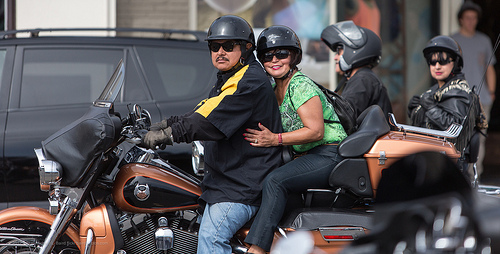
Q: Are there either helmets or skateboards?
A: Yes, there is a helmet.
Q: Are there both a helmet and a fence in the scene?
A: No, there is a helmet but no fences.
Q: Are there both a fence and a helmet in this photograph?
A: No, there is a helmet but no fences.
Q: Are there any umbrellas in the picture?
A: No, there are no umbrellas.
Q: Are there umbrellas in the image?
A: No, there are no umbrellas.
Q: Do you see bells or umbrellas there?
A: No, there are no umbrellas or bells.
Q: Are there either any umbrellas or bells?
A: No, there are no umbrellas or bells.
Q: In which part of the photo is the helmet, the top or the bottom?
A: The helmet is in the top of the image.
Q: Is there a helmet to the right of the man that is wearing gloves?
A: Yes, there is a helmet to the right of the man.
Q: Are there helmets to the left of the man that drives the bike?
A: No, the helmet is to the right of the man.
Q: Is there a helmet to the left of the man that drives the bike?
A: No, the helmet is to the right of the man.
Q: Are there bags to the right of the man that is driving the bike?
A: No, there is a helmet to the right of the man.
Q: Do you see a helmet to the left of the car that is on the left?
A: No, the helmet is to the right of the car.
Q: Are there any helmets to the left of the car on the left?
A: No, the helmet is to the right of the car.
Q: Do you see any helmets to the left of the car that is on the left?
A: No, the helmet is to the right of the car.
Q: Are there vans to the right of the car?
A: No, there is a helmet to the right of the car.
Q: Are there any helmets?
A: Yes, there is a helmet.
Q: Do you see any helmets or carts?
A: Yes, there is a helmet.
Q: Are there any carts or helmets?
A: Yes, there is a helmet.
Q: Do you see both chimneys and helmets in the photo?
A: No, there is a helmet but no chimneys.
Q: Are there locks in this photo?
A: No, there are no locks.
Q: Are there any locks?
A: No, there are no locks.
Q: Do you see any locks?
A: No, there are no locks.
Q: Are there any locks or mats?
A: No, there are no locks or mats.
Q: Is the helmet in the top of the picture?
A: Yes, the helmet is in the top of the image.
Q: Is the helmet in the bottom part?
A: No, the helmet is in the top of the image.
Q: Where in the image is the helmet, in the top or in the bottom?
A: The helmet is in the top of the image.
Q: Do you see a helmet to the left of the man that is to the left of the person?
A: Yes, there is a helmet to the left of the man.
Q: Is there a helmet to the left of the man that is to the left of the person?
A: Yes, there is a helmet to the left of the man.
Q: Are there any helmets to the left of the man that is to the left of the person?
A: Yes, there is a helmet to the left of the man.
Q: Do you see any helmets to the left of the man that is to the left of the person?
A: Yes, there is a helmet to the left of the man.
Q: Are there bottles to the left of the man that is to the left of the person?
A: No, there is a helmet to the left of the man.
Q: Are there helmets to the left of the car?
A: No, the helmet is to the right of the car.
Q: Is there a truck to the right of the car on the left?
A: No, there is a helmet to the right of the car.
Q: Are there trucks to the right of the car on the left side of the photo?
A: No, there is a helmet to the right of the car.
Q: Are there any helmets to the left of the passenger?
A: Yes, there is a helmet to the left of the passenger.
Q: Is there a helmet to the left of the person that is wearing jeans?
A: Yes, there is a helmet to the left of the passenger.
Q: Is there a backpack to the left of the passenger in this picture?
A: No, there is a helmet to the left of the passenger.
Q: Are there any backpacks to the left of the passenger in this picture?
A: No, there is a helmet to the left of the passenger.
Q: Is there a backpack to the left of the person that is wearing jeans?
A: No, there is a helmet to the left of the passenger.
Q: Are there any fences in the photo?
A: No, there are no fences.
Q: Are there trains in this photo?
A: No, there are no trains.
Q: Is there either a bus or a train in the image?
A: No, there are no trains or buses.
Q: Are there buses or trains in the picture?
A: No, there are no trains or buses.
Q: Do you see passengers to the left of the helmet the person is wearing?
A: Yes, there is a passenger to the left of the helmet.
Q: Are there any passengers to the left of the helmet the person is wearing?
A: Yes, there is a passenger to the left of the helmet.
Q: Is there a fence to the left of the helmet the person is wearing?
A: No, there is a passenger to the left of the helmet.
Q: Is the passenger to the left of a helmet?
A: Yes, the passenger is to the left of a helmet.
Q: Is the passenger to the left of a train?
A: No, the passenger is to the left of a helmet.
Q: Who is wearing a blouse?
A: The passenger is wearing a blouse.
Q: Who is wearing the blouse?
A: The passenger is wearing a blouse.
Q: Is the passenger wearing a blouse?
A: Yes, the passenger is wearing a blouse.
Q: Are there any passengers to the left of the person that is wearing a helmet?
A: Yes, there is a passenger to the left of the person.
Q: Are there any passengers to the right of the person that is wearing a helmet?
A: No, the passenger is to the left of the person.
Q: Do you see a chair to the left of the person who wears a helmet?
A: No, there is a passenger to the left of the person.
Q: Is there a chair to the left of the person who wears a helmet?
A: No, there is a passenger to the left of the person.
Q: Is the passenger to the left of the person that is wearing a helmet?
A: Yes, the passenger is to the left of the person.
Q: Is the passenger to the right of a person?
A: No, the passenger is to the left of a person.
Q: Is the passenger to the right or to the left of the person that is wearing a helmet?
A: The passenger is to the left of the person.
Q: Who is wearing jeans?
A: The passenger is wearing jeans.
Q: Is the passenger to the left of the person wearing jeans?
A: Yes, the passenger is wearing jeans.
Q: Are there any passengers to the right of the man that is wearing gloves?
A: Yes, there is a passenger to the right of the man.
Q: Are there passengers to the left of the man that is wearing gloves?
A: No, the passenger is to the right of the man.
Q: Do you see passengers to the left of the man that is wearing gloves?
A: No, the passenger is to the right of the man.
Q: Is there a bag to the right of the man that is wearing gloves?
A: No, there is a passenger to the right of the man.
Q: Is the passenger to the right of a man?
A: Yes, the passenger is to the right of a man.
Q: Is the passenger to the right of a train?
A: No, the passenger is to the right of a man.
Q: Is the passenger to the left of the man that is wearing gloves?
A: No, the passenger is to the right of the man.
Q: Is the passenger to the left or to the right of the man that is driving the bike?
A: The passenger is to the right of the man.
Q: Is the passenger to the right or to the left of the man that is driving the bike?
A: The passenger is to the right of the man.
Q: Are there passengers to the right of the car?
A: Yes, there is a passenger to the right of the car.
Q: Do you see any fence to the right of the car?
A: No, there is a passenger to the right of the car.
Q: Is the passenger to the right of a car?
A: Yes, the passenger is to the right of a car.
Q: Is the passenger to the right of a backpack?
A: No, the passenger is to the right of a car.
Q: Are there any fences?
A: No, there are no fences.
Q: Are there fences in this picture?
A: No, there are no fences.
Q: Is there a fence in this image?
A: No, there are no fences.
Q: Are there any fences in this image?
A: No, there are no fences.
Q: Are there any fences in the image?
A: No, there are no fences.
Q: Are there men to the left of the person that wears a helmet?
A: Yes, there is a man to the left of the person.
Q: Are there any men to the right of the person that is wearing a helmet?
A: No, the man is to the left of the person.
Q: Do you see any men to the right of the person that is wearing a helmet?
A: No, the man is to the left of the person.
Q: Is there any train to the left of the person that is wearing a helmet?
A: No, there is a man to the left of the person.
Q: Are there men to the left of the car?
A: No, the man is to the right of the car.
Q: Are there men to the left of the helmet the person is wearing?
A: Yes, there is a man to the left of the helmet.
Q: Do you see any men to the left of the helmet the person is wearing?
A: Yes, there is a man to the left of the helmet.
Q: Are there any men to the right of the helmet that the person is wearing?
A: No, the man is to the left of the helmet.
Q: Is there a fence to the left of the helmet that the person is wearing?
A: No, there is a man to the left of the helmet.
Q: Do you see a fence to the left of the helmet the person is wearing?
A: No, there is a man to the left of the helmet.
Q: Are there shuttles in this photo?
A: No, there are no shuttles.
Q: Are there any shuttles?
A: No, there are no shuttles.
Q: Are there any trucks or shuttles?
A: No, there are no shuttles or trucks.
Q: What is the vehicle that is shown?
A: The vehicle is a car.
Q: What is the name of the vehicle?
A: The vehicle is a car.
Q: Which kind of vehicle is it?
A: The vehicle is a car.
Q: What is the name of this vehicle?
A: This is a car.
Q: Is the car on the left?
A: Yes, the car is on the left of the image.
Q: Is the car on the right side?
A: No, the car is on the left of the image.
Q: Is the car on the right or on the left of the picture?
A: The car is on the left of the image.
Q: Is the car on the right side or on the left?
A: The car is on the left of the image.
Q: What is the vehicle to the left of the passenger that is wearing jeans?
A: The vehicle is a car.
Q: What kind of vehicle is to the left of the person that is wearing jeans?
A: The vehicle is a car.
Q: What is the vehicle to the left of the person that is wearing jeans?
A: The vehicle is a car.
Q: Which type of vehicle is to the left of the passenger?
A: The vehicle is a car.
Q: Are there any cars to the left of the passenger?
A: Yes, there is a car to the left of the passenger.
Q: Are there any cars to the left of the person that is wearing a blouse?
A: Yes, there is a car to the left of the passenger.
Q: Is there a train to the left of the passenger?
A: No, there is a car to the left of the passenger.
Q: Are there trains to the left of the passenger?
A: No, there is a car to the left of the passenger.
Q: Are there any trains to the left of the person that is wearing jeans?
A: No, there is a car to the left of the passenger.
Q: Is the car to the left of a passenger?
A: Yes, the car is to the left of a passenger.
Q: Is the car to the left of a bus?
A: No, the car is to the left of a passenger.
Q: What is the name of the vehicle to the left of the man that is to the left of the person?
A: The vehicle is a car.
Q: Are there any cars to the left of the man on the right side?
A: Yes, there is a car to the left of the man.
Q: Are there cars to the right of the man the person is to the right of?
A: No, the car is to the left of the man.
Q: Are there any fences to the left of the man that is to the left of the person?
A: No, there is a car to the left of the man.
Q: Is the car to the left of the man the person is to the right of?
A: Yes, the car is to the left of the man.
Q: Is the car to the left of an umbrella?
A: No, the car is to the left of the man.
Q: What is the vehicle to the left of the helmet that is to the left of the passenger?
A: The vehicle is a car.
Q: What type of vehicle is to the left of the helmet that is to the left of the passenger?
A: The vehicle is a car.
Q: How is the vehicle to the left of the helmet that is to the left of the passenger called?
A: The vehicle is a car.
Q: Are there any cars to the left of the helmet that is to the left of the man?
A: Yes, there is a car to the left of the helmet.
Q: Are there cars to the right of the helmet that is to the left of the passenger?
A: No, the car is to the left of the helmet.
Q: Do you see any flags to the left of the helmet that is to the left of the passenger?
A: No, there is a car to the left of the helmet.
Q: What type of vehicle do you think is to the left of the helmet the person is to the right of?
A: The vehicle is a car.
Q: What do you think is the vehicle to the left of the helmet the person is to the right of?
A: The vehicle is a car.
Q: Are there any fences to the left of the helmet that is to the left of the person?
A: No, there is a car to the left of the helmet.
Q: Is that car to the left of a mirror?
A: No, the car is to the left of a helmet.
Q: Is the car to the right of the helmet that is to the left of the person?
A: No, the car is to the left of the helmet.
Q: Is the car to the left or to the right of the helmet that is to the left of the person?
A: The car is to the left of the helmet.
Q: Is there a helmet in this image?
A: Yes, there is a helmet.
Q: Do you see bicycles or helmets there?
A: Yes, there is a helmet.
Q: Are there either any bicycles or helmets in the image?
A: Yes, there is a helmet.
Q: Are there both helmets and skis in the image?
A: No, there is a helmet but no skis.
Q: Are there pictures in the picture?
A: No, there are no pictures.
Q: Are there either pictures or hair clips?
A: No, there are no pictures or hair clips.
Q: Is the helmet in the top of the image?
A: Yes, the helmet is in the top of the image.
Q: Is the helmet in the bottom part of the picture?
A: No, the helmet is in the top of the image.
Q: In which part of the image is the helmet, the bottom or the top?
A: The helmet is in the top of the image.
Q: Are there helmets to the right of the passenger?
A: Yes, there is a helmet to the right of the passenger.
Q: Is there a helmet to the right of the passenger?
A: Yes, there is a helmet to the right of the passenger.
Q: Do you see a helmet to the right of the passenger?
A: Yes, there is a helmet to the right of the passenger.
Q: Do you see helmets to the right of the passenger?
A: Yes, there is a helmet to the right of the passenger.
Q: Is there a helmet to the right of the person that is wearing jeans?
A: Yes, there is a helmet to the right of the passenger.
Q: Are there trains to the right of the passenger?
A: No, there is a helmet to the right of the passenger.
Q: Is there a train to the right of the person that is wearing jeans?
A: No, there is a helmet to the right of the passenger.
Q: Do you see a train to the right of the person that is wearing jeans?
A: No, there is a helmet to the right of the passenger.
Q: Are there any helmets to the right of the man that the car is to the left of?
A: Yes, there is a helmet to the right of the man.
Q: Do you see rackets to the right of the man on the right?
A: No, there is a helmet to the right of the man.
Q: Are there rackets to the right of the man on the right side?
A: No, there is a helmet to the right of the man.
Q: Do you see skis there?
A: No, there are no skis.